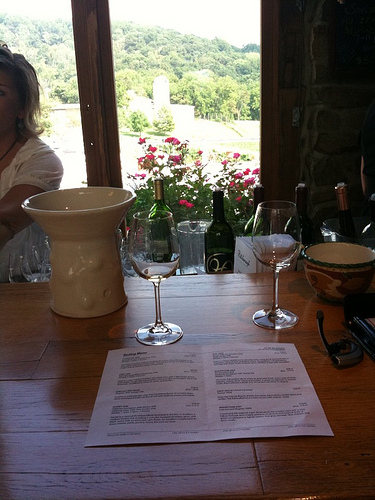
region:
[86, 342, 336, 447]
white paper restaurant menu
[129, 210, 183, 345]
empty wine glass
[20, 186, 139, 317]
white ceramic vase with wide opening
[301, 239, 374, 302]
small painted terra cotta bowl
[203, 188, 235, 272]
bottle of wine with black label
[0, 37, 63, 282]
woman with blonde hair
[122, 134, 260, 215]
pink roses outside restaurant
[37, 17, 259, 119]
hill of leafy trees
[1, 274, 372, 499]
brown wood table top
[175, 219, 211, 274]
empty glass water pitcher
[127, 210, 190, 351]
wine glass on table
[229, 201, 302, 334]
wine glass on table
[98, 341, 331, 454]
menu on wooden table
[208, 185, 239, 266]
wine bottle on table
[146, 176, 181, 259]
wine bottle on table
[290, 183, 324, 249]
wine bottle on table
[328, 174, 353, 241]
wine bottle on table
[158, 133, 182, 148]
pink flower on plant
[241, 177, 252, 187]
pink flower on plant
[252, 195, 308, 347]
a clear wine glass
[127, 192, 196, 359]
a clear wine glass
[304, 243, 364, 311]
a ceramic bowl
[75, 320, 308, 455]
a menu for a restraunt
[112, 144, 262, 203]
pink flowers in the background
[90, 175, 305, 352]
two empty wine glasses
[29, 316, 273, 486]
a wooden plank table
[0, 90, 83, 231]
a woman in a white shirt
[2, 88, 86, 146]
a woman with blonde hair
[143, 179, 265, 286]
two bottles of wine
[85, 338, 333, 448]
a paper is on the table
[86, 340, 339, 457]
a menu is on the table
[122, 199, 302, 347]
two empty wine glasses are on the table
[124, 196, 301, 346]
the wine glasses are empty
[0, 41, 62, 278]
a woman is sitting at the table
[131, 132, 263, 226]
a plant with pink flowers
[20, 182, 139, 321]
a white ceramic container on the table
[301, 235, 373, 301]
a bowl on the table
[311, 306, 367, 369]
a bluetooth headpiece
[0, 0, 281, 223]
a window is behind the woman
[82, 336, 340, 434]
Open menu on a wooden table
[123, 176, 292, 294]
Two empty wine glasses on the wooden table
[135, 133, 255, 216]
Pink flowers by the window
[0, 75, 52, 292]
Woman standing behind the table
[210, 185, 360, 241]
Wine bottles behind the table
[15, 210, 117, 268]
Wine glasses on the counter besides the woman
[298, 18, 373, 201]
An interior stone wall beside the window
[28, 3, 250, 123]
A field can be seen outside of the window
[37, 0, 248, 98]
Tree-covered mountains are seen outside of the window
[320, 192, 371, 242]
Wine in an ice bucket